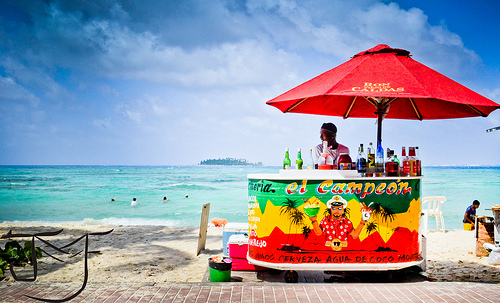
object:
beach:
[1, 216, 500, 281]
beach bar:
[247, 142, 424, 282]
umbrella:
[265, 44, 499, 148]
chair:
[421, 194, 448, 232]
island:
[200, 157, 263, 166]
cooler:
[229, 234, 256, 271]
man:
[462, 200, 479, 230]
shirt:
[462, 206, 475, 223]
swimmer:
[111, 197, 116, 202]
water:
[1, 165, 500, 226]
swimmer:
[130, 197, 138, 206]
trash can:
[209, 256, 231, 282]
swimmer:
[163, 195, 168, 203]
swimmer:
[185, 194, 189, 199]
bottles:
[283, 146, 293, 171]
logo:
[349, 80, 406, 93]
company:
[286, 179, 413, 199]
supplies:
[221, 221, 270, 271]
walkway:
[0, 280, 499, 302]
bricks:
[250, 282, 265, 302]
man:
[312, 122, 348, 167]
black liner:
[208, 262, 228, 271]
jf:
[8, 227, 114, 302]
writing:
[352, 81, 404, 92]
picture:
[280, 195, 399, 252]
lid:
[228, 234, 248, 245]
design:
[282, 187, 397, 253]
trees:
[279, 198, 299, 251]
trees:
[217, 157, 224, 163]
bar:
[241, 169, 424, 280]